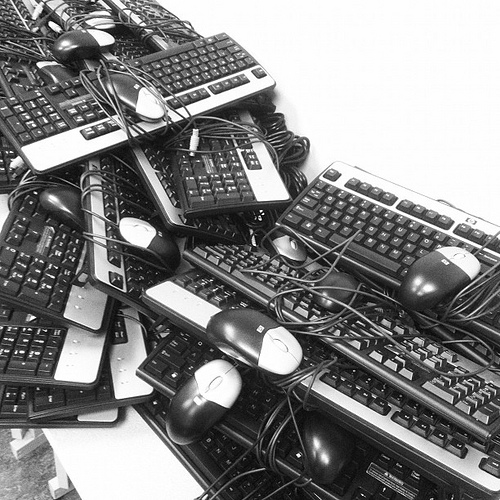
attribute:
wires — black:
[7, 6, 485, 481]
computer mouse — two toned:
[151, 355, 261, 454]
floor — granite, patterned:
[2, 425, 73, 499]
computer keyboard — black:
[273, 160, 500, 348]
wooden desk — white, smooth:
[9, 0, 499, 499]